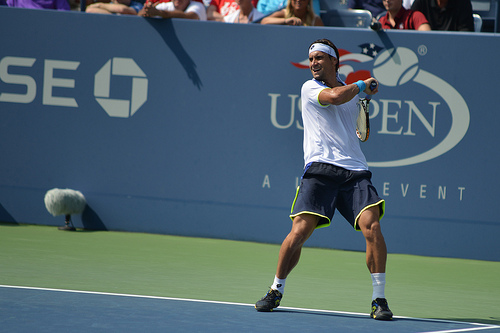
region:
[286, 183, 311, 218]
yellow stripe on blue shorts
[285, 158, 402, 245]
disheveled blue tennis shorts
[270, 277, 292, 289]
symbol on white socks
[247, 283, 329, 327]
black sneakers with laces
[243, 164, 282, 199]
white word on blue background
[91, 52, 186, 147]
white octagon in bold letters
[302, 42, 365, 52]
white headband on man's head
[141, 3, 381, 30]
spectators sitting in sand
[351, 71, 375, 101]
blue wrist band on hand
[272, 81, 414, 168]
white tee shirt on man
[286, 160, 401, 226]
blue tennis shorts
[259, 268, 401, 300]
white athletic socks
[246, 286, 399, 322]
dark colored tennis shoes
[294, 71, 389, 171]
white athletic top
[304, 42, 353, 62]
white athletic headband with an emblem in the front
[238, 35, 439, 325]
man playing tennis with an opponent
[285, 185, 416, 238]
muscular quadriceps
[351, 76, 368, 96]
light blue athletic wrist band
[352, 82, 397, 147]
tennis racket in swinging motio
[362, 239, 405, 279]
muscular calves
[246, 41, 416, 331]
male tennis player in a competition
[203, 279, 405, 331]
male tennis player's sneakers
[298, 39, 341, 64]
male tennis player wearing white headband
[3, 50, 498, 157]
advertising behind tennis game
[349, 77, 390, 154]
male tennis player's tennis racket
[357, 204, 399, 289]
muscular leg on tennis player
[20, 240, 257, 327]
tennis court during tennis match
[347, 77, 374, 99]
male tennis player wearing blue wrist band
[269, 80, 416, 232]
male tennis player wearing blue shorts and white t-shirt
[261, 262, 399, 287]
tennis player wearing white socks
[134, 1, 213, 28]
These are brown arms.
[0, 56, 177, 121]
This is the Chase logo.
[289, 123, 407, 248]
These are shorts.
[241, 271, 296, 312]
This is the right shoe.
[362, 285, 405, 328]
This is the left shoe.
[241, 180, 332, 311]
This is the right leg.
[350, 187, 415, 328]
This is the left leg.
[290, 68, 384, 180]
This is a white tshirt.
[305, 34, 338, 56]
This is a headband.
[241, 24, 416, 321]
This is a tennis player.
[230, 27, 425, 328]
A man playing tennis.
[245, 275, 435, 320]
The man is wearing black sneakers.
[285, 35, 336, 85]
The man is wearing a headband.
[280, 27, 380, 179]
The man is holding a tennis racket in his right hand.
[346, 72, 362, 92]
A blue armband.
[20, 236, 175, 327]
The tennis court.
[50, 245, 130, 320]
The court is green and blue.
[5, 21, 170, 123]
A corporate sponsor of the event.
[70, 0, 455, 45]
People in the stands watching the match.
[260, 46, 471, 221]
The name of the event written on the wall.